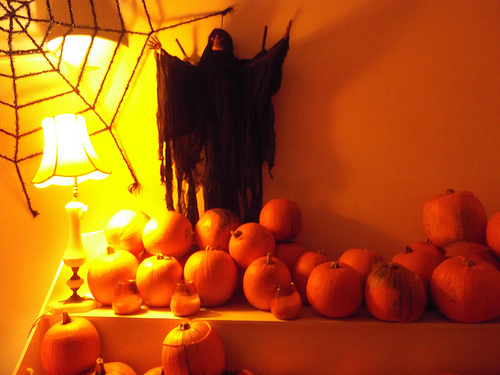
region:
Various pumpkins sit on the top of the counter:
[91, 210, 472, 323]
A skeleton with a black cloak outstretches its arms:
[150, 12, 307, 215]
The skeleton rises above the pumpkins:
[129, 17, 321, 240]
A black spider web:
[6, 0, 157, 228]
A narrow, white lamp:
[26, 103, 118, 322]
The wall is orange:
[287, 17, 470, 187]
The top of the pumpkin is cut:
[139, 315, 234, 368]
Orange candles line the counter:
[96, 270, 226, 324]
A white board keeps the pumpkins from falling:
[11, 219, 188, 364]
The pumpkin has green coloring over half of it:
[358, 255, 438, 330]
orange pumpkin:
[414, 186, 489, 247]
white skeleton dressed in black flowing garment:
[143, 15, 306, 200]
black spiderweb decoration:
[1, 2, 143, 101]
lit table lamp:
[30, 108, 105, 310]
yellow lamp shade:
[28, 113, 116, 189]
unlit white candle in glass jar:
[263, 278, 305, 325]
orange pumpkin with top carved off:
[151, 317, 234, 374]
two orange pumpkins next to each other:
[359, 259, 499, 334]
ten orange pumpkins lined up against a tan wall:
[308, 180, 497, 320]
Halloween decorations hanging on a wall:
[52, 8, 321, 103]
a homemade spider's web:
[8, 10, 153, 121]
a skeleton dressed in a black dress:
[146, 8, 292, 216]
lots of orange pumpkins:
[212, 217, 485, 312]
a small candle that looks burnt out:
[112, 275, 143, 313]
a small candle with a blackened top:
[171, 280, 202, 310]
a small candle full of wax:
[270, 280, 303, 315]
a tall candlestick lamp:
[53, 190, 84, 311]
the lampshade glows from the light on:
[33, 111, 108, 206]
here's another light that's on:
[32, 0, 132, 55]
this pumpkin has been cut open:
[167, 315, 219, 369]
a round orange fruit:
[430, 255, 497, 324]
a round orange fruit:
[361, 259, 423, 321]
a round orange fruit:
[306, 248, 356, 320]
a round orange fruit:
[243, 252, 292, 307]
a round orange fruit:
[165, 322, 218, 373]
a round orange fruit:
[36, 310, 108, 368]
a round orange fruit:
[138, 251, 188, 310]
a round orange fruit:
[88, 240, 141, 305]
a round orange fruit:
[224, 215, 276, 260]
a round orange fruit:
[258, 194, 310, 246]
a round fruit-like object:
[188, 244, 234, 304]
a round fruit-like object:
[156, 315, 223, 371]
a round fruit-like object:
[36, 313, 96, 373]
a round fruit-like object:
[305, 257, 370, 325]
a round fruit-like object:
[368, 260, 423, 324]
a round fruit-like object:
[431, 242, 498, 329]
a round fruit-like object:
[420, 182, 484, 241]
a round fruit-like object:
[253, 195, 299, 242]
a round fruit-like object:
[227, 222, 274, 279]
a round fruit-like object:
[195, 205, 236, 250]